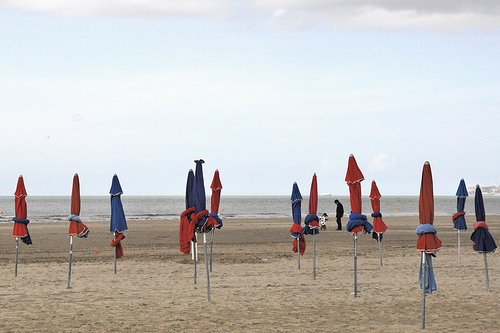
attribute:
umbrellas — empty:
[11, 152, 495, 293]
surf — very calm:
[8, 177, 495, 224]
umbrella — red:
[11, 172, 31, 278]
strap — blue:
[11, 215, 29, 222]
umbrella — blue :
[108, 174, 128, 271]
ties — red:
[107, 157, 221, 277]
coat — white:
[319, 216, 327, 226]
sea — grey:
[2, 186, 499, 227]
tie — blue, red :
[415, 223, 438, 294]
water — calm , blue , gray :
[0, 194, 499, 219]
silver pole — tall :
[67, 232, 72, 295]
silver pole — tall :
[199, 232, 214, 300]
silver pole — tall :
[417, 252, 428, 328]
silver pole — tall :
[310, 229, 318, 279]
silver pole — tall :
[482, 256, 492, 289]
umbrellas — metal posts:
[10, 159, 497, 249]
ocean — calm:
[1, 194, 499, 221]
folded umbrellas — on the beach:
[22, 153, 490, 293]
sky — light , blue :
[6, 8, 498, 197]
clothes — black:
[332, 205, 346, 226]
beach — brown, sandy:
[10, 195, 499, 331]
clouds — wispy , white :
[69, 54, 424, 126]